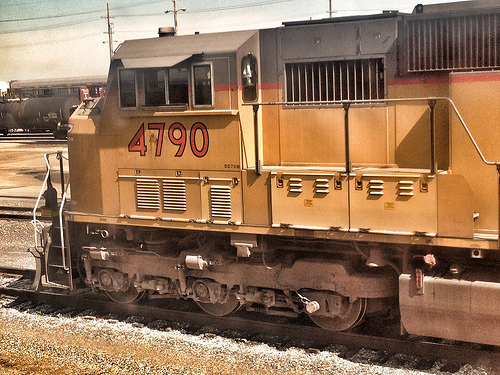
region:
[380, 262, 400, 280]
part of a train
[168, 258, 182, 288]
part of a locomotive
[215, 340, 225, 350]
part of the grass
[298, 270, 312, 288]
edge of a wheel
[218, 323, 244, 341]
part of a rail way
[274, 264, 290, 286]
part of a train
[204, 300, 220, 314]
edge of a wheel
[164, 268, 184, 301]
part of a train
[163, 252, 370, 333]
wheels on the train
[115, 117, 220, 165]
numbers on the train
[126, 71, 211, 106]
windows on the train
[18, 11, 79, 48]
electrical lines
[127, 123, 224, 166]
the numbers are red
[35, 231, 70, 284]
stairs on the train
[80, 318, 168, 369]
dirt on the ground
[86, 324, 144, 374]
the dirt is brown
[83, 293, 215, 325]
the train is on the tracks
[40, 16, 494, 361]
a brown old train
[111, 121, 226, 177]
the train has a number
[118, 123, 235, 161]
the number is written in a red colour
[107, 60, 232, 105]
it has windows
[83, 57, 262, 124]
the windows are closed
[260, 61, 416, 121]
it has railings on windows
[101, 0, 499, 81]
the top part is black in colour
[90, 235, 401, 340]
the wheels are brown in colour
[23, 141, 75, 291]
it has a metal railing on the front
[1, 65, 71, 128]
the train iis black in colour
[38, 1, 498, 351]
a yellow and black train engine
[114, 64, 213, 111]
a train engine side window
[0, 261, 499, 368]
a set of train tracks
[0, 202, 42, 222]
a set of train tracks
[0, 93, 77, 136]
a train coal car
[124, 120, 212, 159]
printed train number 4790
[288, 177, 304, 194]
a set of three ventilations slots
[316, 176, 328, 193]
a set of three ventilations slots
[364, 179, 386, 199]
a set of three ventilations slots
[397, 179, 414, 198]
a set of three ventilations slots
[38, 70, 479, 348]
Yellow locomotive on tracks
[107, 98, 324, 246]
Number 4790 on a train